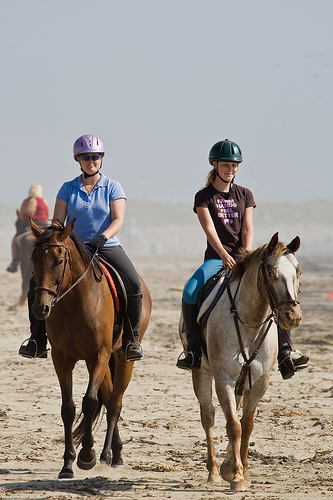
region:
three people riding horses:
[6, 133, 307, 488]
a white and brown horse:
[175, 231, 303, 486]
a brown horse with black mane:
[25, 213, 152, 479]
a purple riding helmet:
[72, 132, 105, 175]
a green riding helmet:
[205, 133, 242, 182]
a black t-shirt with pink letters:
[189, 182, 255, 261]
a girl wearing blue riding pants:
[183, 256, 229, 304]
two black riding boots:
[174, 297, 310, 379]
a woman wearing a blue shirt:
[54, 173, 128, 251]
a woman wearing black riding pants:
[25, 242, 141, 294]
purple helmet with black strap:
[69, 132, 108, 176]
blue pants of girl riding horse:
[176, 257, 245, 309]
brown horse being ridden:
[15, 210, 148, 473]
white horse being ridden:
[176, 244, 311, 476]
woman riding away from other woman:
[14, 181, 52, 317]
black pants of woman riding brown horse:
[24, 241, 143, 341]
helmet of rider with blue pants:
[210, 134, 238, 181]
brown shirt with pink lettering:
[183, 180, 253, 251]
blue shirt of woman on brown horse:
[60, 174, 123, 242]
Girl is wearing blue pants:
[179, 252, 233, 308]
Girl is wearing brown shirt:
[192, 178, 254, 262]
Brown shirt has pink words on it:
[191, 180, 259, 262]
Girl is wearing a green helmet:
[204, 136, 247, 184]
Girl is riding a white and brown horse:
[176, 136, 310, 494]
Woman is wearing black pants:
[24, 240, 145, 348]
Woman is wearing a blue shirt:
[54, 172, 125, 250]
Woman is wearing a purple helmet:
[72, 131, 106, 157]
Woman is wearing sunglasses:
[78, 152, 103, 161]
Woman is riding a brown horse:
[18, 131, 154, 480]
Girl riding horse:
[188, 139, 308, 484]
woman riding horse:
[28, 133, 140, 478]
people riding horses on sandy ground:
[6, 134, 316, 489]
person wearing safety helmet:
[71, 133, 104, 177]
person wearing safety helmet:
[207, 134, 241, 187]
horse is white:
[172, 240, 314, 484]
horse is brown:
[20, 218, 159, 482]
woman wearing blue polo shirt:
[48, 133, 129, 248]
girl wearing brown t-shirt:
[192, 180, 258, 264]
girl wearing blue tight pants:
[162, 135, 312, 379]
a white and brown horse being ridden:
[168, 231, 315, 456]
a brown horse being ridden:
[17, 206, 148, 483]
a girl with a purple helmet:
[35, 97, 140, 253]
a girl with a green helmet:
[176, 102, 271, 262]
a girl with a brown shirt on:
[166, 109, 275, 291]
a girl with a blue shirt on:
[34, 113, 143, 262]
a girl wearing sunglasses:
[36, 113, 137, 252]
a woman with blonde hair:
[8, 170, 53, 233]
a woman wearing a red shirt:
[15, 178, 53, 240]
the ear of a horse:
[18, 210, 47, 237]